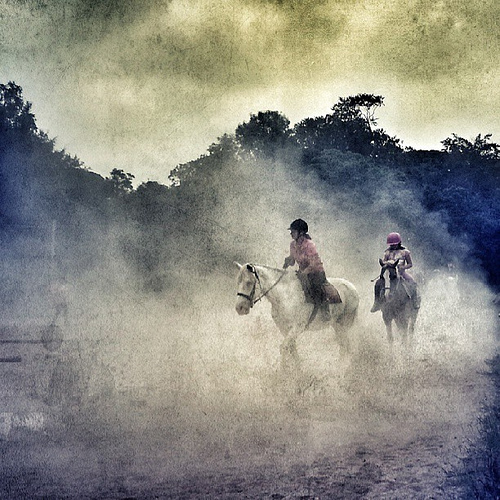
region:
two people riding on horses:
[211, 212, 428, 382]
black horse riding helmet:
[290, 214, 309, 233]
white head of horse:
[228, 259, 261, 307]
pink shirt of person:
[288, 233, 323, 269]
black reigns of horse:
[266, 263, 293, 283]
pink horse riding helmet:
[386, 230, 400, 245]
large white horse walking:
[226, 254, 363, 387]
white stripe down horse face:
[376, 267, 394, 299]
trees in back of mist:
[272, 135, 479, 183]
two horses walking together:
[205, 147, 489, 469]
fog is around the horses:
[135, 151, 469, 428]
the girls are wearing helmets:
[244, 192, 434, 302]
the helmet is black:
[261, 187, 320, 249]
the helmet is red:
[364, 224, 419, 257]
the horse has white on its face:
[370, 258, 402, 305]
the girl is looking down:
[350, 202, 421, 280]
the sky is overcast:
[85, 37, 460, 159]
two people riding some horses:
[246, 207, 427, 344]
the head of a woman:
[282, 215, 307, 240]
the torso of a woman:
[290, 240, 323, 272]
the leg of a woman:
[306, 272, 331, 310]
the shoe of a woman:
[323, 304, 334, 321]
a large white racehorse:
[222, 261, 359, 367]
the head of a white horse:
[219, 252, 259, 315]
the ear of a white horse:
[223, 259, 261, 276]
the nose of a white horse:
[233, 295, 253, 313]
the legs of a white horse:
[273, 317, 301, 362]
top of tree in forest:
[0, 80, 22, 122]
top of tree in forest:
[19, 98, 40, 134]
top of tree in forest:
[111, 166, 136, 193]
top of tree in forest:
[163, 128, 238, 183]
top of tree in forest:
[233, 104, 294, 154]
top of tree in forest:
[287, 110, 328, 146]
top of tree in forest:
[334, 86, 386, 118]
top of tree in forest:
[366, 123, 407, 155]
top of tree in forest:
[440, 121, 499, 159]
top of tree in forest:
[137, 181, 170, 191]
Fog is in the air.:
[4, 155, 491, 462]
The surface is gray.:
[1, 437, 491, 497]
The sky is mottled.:
[1, 0, 498, 185]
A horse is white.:
[233, 263, 365, 390]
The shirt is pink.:
[287, 240, 324, 276]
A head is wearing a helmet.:
[287, 220, 308, 242]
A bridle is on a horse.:
[233, 262, 273, 316]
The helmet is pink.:
[387, 234, 402, 248]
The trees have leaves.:
[1, 74, 492, 261]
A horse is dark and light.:
[371, 257, 425, 339]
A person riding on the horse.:
[277, 215, 343, 320]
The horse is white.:
[228, 265, 365, 354]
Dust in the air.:
[62, 225, 297, 424]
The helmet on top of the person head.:
[383, 228, 414, 249]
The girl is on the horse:
[223, 152, 373, 404]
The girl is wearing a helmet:
[272, 220, 342, 296]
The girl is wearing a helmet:
[366, 230, 433, 308]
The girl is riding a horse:
[230, 175, 375, 392]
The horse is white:
[226, 255, 366, 385]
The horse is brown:
[367, 258, 442, 359]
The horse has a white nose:
[369, 258, 434, 358]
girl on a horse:
[285, 218, 336, 323]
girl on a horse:
[372, 234, 415, 311]